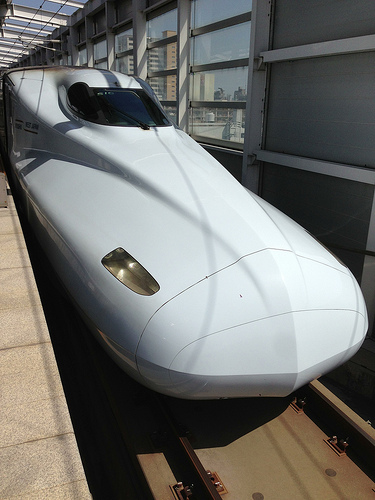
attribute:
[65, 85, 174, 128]
windows — dark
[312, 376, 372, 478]
track — metal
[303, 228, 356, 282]
headlight — unseen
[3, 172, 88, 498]
tiles — concrete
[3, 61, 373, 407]
vehicle — white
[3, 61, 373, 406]
train — white , Japanese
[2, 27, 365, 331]
vehicle — white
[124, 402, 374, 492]
tracks — brown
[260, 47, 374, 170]
paneling — grey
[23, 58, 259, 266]
train — black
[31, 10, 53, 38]
suspension line — metal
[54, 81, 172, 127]
window — black, tented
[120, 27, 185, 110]
building — tall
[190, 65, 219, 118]
building — tall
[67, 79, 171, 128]
windshield — black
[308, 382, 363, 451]
track — metal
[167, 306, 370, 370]
line — black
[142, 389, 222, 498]
rod — steel